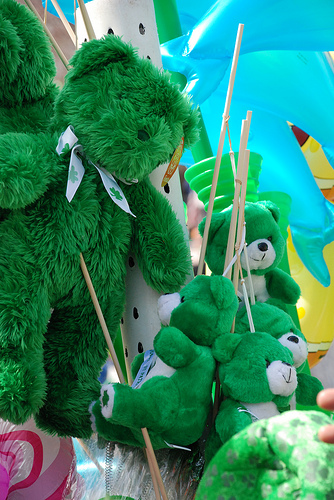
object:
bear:
[0, 34, 197, 442]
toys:
[89, 275, 239, 453]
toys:
[164, 0, 334, 108]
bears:
[198, 194, 303, 365]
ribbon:
[56, 124, 140, 229]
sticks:
[197, 12, 243, 270]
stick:
[78, 252, 169, 500]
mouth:
[118, 137, 141, 165]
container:
[183, 150, 264, 206]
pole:
[192, 16, 242, 277]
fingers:
[312, 383, 334, 416]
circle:
[0, 428, 46, 489]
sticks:
[226, 99, 255, 307]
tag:
[106, 181, 138, 217]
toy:
[213, 331, 300, 441]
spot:
[220, 471, 235, 490]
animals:
[95, 273, 236, 444]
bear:
[90, 272, 240, 447]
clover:
[304, 454, 332, 485]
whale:
[157, 0, 334, 110]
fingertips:
[311, 389, 327, 414]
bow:
[28, 143, 89, 216]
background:
[147, 0, 334, 180]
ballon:
[1, 421, 76, 499]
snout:
[254, 240, 271, 254]